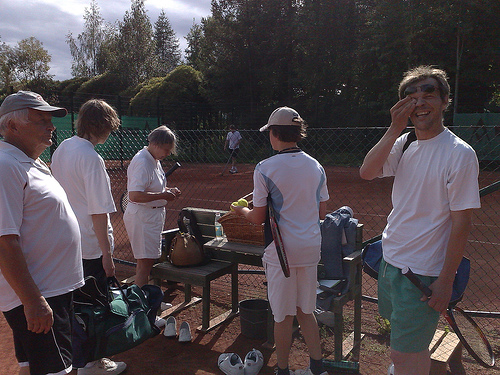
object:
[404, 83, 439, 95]
sunglasses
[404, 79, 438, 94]
forehead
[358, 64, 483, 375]
man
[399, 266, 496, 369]
racket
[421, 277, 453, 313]
hand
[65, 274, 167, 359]
bag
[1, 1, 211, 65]
skies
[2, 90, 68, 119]
cap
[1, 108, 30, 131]
hair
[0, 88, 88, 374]
man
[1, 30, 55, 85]
trees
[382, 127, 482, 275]
shirt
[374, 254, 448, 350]
shorts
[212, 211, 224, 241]
bottle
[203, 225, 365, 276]
table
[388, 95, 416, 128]
hand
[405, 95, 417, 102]
eye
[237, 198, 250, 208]
balls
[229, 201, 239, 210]
balls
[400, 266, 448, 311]
handle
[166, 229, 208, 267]
bag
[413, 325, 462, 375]
bench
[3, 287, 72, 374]
shorts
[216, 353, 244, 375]
shoes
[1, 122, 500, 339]
fence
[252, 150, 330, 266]
shirt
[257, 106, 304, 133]
hat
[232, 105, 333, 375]
man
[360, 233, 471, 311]
bag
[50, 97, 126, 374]
man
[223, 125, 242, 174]
man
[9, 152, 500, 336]
court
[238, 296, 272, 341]
bucket